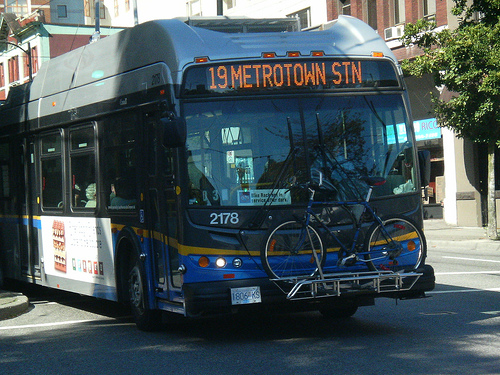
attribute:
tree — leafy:
[401, 3, 499, 153]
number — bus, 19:
[205, 59, 232, 97]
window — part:
[181, 91, 419, 210]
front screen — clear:
[182, 91, 423, 211]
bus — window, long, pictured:
[1, 11, 436, 337]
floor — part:
[386, 326, 466, 367]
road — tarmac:
[6, 332, 499, 372]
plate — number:
[225, 284, 265, 306]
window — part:
[250, 110, 323, 160]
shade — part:
[358, 323, 458, 373]